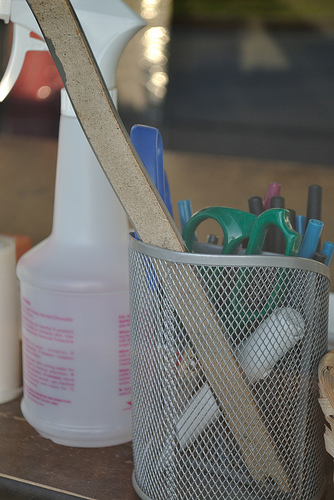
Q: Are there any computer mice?
A: No, there are no computer mice.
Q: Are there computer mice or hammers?
A: No, there are no computer mice or hammers.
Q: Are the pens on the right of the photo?
A: Yes, the pens are on the right of the image.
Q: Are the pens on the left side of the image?
A: No, the pens are on the right of the image.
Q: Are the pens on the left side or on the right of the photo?
A: The pens are on the right of the image.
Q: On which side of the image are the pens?
A: The pens are on the right of the image.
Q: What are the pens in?
A: The pens are in the container.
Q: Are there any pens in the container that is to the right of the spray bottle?
A: Yes, there are pens in the container.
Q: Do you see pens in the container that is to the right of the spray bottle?
A: Yes, there are pens in the container.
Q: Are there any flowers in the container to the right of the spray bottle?
A: No, there are pens in the container.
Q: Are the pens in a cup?
A: No, the pens are in a container.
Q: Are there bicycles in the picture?
A: No, there are no bicycles.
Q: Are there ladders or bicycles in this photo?
A: No, there are no bicycles or ladders.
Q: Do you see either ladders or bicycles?
A: No, there are no bicycles or ladders.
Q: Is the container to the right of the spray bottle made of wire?
A: Yes, the container is made of wire.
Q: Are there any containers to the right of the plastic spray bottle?
A: Yes, there is a container to the right of the spray bottle.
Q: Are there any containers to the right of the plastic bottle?
A: Yes, there is a container to the right of the spray bottle.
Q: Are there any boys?
A: No, there are no boys.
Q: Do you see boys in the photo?
A: No, there are no boys.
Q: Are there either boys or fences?
A: No, there are no boys or fences.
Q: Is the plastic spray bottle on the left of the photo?
A: Yes, the spray bottle is on the left of the image.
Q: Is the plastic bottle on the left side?
A: Yes, the spray bottle is on the left of the image.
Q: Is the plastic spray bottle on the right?
A: No, the spray bottle is on the left of the image.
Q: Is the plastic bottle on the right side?
A: No, the spray bottle is on the left of the image.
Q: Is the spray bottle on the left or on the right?
A: The spray bottle is on the left of the image.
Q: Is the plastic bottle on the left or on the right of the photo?
A: The spray bottle is on the left of the image.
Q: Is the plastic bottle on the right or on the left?
A: The spray bottle is on the left of the image.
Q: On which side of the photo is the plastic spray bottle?
A: The spray bottle is on the left of the image.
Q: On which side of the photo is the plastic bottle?
A: The spray bottle is on the left of the image.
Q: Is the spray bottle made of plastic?
A: Yes, the spray bottle is made of plastic.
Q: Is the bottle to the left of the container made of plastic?
A: Yes, the spray bottle is made of plastic.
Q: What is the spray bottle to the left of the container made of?
A: The spray bottle is made of plastic.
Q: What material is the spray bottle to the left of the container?
A: The spray bottle is made of plastic.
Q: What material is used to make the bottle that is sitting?
A: The spray bottle is made of plastic.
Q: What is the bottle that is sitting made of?
A: The spray bottle is made of plastic.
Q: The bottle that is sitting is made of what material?
A: The spray bottle is made of plastic.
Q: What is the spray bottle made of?
A: The spray bottle is made of plastic.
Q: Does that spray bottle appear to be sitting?
A: Yes, the spray bottle is sitting.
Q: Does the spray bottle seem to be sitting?
A: Yes, the spray bottle is sitting.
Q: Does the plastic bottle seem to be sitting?
A: Yes, the spray bottle is sitting.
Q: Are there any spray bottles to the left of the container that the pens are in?
A: Yes, there is a spray bottle to the left of the container.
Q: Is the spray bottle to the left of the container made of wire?
A: Yes, the spray bottle is to the left of the container.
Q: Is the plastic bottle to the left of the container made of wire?
A: Yes, the spray bottle is to the left of the container.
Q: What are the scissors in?
A: The scissors are in the container.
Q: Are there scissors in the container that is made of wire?
A: Yes, there are scissors in the container.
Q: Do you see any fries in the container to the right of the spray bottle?
A: No, there are scissors in the container.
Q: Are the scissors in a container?
A: Yes, the scissors are in a container.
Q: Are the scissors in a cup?
A: No, the scissors are in a container.